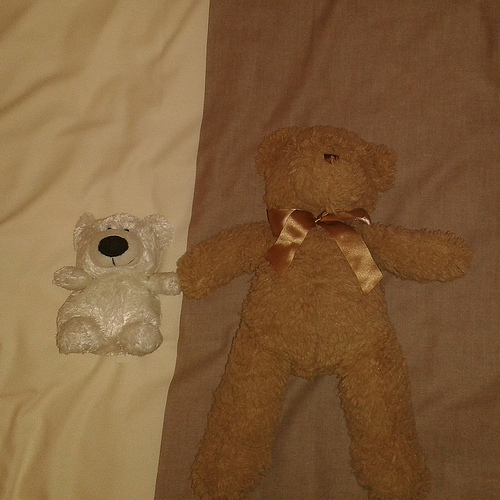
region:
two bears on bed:
[46, 93, 468, 478]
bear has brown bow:
[208, 189, 423, 311]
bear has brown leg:
[346, 307, 421, 494]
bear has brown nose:
[303, 128, 363, 185]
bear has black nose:
[86, 232, 147, 275]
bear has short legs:
[41, 252, 171, 362]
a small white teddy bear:
[50, 211, 180, 358]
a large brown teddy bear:
[175, 126, 473, 496]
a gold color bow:
[261, 202, 382, 294]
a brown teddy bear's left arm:
[368, 220, 469, 281]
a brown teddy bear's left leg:
[339, 337, 436, 497]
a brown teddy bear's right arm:
[178, 219, 268, 301]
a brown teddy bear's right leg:
[187, 332, 292, 497]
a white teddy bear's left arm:
[147, 271, 181, 296]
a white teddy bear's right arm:
[52, 268, 92, 292]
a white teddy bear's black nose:
[99, 234, 129, 258]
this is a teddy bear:
[166, 115, 490, 497]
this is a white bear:
[31, 178, 179, 375]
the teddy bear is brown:
[183, 109, 474, 491]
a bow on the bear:
[247, 182, 389, 297]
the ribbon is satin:
[260, 190, 399, 305]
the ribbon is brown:
[241, 196, 396, 291]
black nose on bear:
[88, 228, 140, 268]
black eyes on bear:
[101, 213, 140, 235]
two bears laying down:
[11, 107, 486, 494]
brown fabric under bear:
[141, 121, 498, 485]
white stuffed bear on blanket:
[50, 207, 185, 363]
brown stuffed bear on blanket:
[172, 115, 473, 498]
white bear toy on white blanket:
[45, 208, 189, 364]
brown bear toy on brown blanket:
[175, 121, 477, 498]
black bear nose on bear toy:
[95, 231, 131, 261]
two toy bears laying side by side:
[42, 113, 489, 498]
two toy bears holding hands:
[37, 114, 487, 499]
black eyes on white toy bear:
[102, 223, 131, 235]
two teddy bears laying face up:
[52, 122, 472, 498]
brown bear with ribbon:
[179, 126, 476, 498]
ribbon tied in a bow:
[262, 205, 384, 290]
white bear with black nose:
[54, 211, 177, 352]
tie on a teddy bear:
[261, 201, 388, 300]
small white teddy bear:
[48, 203, 188, 364]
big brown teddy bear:
[171, 115, 468, 498]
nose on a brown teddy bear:
[316, 149, 343, 167]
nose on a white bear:
[93, 233, 130, 258]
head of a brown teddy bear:
[249, 113, 401, 228]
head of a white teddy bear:
[71, 205, 173, 282]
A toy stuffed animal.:
[198, 105, 418, 492]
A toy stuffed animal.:
[46, 192, 180, 408]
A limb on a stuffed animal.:
[158, 307, 303, 498]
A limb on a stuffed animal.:
[341, 350, 437, 475]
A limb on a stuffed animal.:
[361, 205, 457, 301]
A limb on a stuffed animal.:
[155, 207, 329, 267]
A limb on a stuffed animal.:
[141, 270, 184, 302]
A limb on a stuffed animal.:
[126, 318, 187, 371]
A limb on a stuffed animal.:
[53, 315, 122, 358]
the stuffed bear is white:
[52, 213, 178, 355]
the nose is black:
[97, 235, 128, 255]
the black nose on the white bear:
[52, 213, 182, 357]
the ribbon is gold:
[264, 205, 382, 292]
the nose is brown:
[323, 153, 339, 163]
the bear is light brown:
[177, 124, 472, 499]